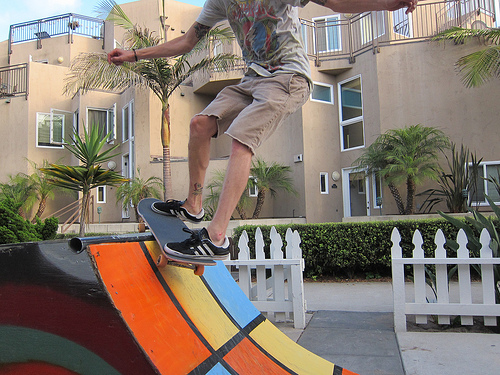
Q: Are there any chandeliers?
A: No, there are no chandeliers.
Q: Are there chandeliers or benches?
A: No, there are no chandeliers or benches.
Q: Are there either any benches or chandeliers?
A: No, there are no chandeliers or benches.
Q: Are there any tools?
A: No, there are no tools.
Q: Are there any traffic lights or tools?
A: No, there are no tools or traffic lights.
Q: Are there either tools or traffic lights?
A: No, there are no tools or traffic lights.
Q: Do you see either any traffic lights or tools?
A: No, there are no tools or traffic lights.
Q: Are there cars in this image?
A: No, there are no cars.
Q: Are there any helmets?
A: No, there are no helmets.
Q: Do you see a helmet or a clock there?
A: No, there are no helmets or clocks.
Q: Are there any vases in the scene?
A: No, there are no vases.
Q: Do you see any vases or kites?
A: No, there are no vases or kites.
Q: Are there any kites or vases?
A: No, there are no vases or kites.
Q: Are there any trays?
A: No, there are no trays.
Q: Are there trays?
A: No, there are no trays.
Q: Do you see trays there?
A: No, there are no trays.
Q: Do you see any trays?
A: No, there are no trays.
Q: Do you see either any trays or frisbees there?
A: No, there are no trays or frisbees.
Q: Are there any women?
A: No, there are no women.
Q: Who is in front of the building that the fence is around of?
A: The man is in front of the building.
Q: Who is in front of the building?
A: The man is in front of the building.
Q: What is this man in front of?
A: The man is in front of the building.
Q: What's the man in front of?
A: The man is in front of the building.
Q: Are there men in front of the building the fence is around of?
A: Yes, there is a man in front of the building.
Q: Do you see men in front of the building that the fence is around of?
A: Yes, there is a man in front of the building.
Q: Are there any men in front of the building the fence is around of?
A: Yes, there is a man in front of the building.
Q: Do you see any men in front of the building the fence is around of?
A: Yes, there is a man in front of the building.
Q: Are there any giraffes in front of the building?
A: No, there is a man in front of the building.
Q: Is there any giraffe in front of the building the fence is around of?
A: No, there is a man in front of the building.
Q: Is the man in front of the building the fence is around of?
A: Yes, the man is in front of the building.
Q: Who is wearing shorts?
A: The man is wearing shorts.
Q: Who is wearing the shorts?
A: The man is wearing shorts.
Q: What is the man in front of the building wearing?
A: The man is wearing shorts.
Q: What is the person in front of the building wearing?
A: The man is wearing shorts.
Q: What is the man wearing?
A: The man is wearing shorts.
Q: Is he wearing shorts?
A: Yes, the man is wearing shorts.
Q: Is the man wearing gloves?
A: No, the man is wearing shorts.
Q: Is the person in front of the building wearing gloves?
A: No, the man is wearing shorts.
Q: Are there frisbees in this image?
A: No, there are no frisbees.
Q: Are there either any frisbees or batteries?
A: No, there are no frisbees or batteries.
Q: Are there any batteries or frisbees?
A: No, there are no frisbees or batteries.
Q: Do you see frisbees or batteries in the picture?
A: No, there are no frisbees or batteries.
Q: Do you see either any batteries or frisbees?
A: No, there are no frisbees or batteries.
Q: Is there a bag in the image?
A: No, there are no bags.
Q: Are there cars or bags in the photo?
A: No, there are no bags or cars.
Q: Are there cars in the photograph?
A: No, there are no cars.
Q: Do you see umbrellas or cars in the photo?
A: No, there are no cars or umbrellas.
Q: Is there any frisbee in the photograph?
A: No, there are no frisbees.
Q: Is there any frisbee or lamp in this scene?
A: No, there are no frisbees or lamps.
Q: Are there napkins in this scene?
A: No, there are no napkins.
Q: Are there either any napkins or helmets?
A: No, there are no napkins or helmets.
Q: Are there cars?
A: No, there are no cars.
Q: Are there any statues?
A: No, there are no statues.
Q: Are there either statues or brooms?
A: No, there are no statues or brooms.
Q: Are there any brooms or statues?
A: No, there are no statues or brooms.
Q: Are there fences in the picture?
A: Yes, there is a fence.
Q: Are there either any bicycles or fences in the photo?
A: Yes, there is a fence.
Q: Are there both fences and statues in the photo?
A: No, there is a fence but no statues.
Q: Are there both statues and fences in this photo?
A: No, there is a fence but no statues.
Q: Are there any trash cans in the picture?
A: No, there are no trash cans.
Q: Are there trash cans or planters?
A: No, there are no trash cans or planters.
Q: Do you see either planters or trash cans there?
A: No, there are no trash cans or planters.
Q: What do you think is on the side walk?
A: The fence is on the side walk.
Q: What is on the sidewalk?
A: The fence is on the side walk.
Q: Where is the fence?
A: The fence is on the sidewalk.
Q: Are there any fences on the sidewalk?
A: Yes, there is a fence on the sidewalk.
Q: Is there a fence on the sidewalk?
A: Yes, there is a fence on the sidewalk.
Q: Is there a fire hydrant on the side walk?
A: No, there is a fence on the side walk.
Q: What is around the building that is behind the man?
A: The fence is around the building.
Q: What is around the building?
A: The fence is around the building.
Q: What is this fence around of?
A: The fence is around the building.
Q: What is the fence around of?
A: The fence is around the building.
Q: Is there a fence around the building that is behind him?
A: Yes, there is a fence around the building.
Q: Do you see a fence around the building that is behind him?
A: Yes, there is a fence around the building.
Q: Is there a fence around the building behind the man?
A: Yes, there is a fence around the building.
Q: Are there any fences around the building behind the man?
A: Yes, there is a fence around the building.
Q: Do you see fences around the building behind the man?
A: Yes, there is a fence around the building.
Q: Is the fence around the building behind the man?
A: Yes, the fence is around the building.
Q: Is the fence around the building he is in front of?
A: Yes, the fence is around the building.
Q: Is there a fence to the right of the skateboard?
A: Yes, there is a fence to the right of the skateboard.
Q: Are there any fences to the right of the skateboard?
A: Yes, there is a fence to the right of the skateboard.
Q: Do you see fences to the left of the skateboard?
A: No, the fence is to the right of the skateboard.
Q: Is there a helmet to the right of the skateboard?
A: No, there is a fence to the right of the skateboard.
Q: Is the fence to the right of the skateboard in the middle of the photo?
A: Yes, the fence is to the right of the skateboard.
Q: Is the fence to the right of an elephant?
A: No, the fence is to the right of the skateboard.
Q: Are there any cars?
A: No, there are no cars.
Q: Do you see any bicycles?
A: No, there are no bicycles.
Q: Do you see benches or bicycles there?
A: No, there are no bicycles or benches.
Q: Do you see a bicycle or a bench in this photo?
A: No, there are no bicycles or benches.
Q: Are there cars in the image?
A: No, there are no cars.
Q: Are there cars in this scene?
A: No, there are no cars.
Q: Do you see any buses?
A: No, there are no buses.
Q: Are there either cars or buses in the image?
A: No, there are no buses or cars.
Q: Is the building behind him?
A: Yes, the building is behind the man.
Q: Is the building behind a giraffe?
A: No, the building is behind the man.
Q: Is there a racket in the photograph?
A: No, there are no rackets.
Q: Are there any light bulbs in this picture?
A: No, there are no light bulbs.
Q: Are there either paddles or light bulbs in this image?
A: No, there are no light bulbs or paddles.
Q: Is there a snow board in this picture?
A: No, there are no snowboards.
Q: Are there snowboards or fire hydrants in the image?
A: No, there are no snowboards or fire hydrants.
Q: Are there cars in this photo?
A: No, there are no cars.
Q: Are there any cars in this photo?
A: No, there are no cars.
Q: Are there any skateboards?
A: Yes, there is a skateboard.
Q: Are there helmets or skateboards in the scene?
A: Yes, there is a skateboard.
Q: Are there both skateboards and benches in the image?
A: No, there is a skateboard but no benches.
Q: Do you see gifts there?
A: No, there are no gifts.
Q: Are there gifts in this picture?
A: No, there are no gifts.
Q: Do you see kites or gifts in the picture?
A: No, there are no gifts or kites.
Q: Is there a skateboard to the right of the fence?
A: No, the skateboard is to the left of the fence.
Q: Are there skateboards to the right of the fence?
A: No, the skateboard is to the left of the fence.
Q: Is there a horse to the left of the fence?
A: No, there is a skateboard to the left of the fence.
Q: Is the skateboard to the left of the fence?
A: Yes, the skateboard is to the left of the fence.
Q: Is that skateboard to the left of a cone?
A: No, the skateboard is to the left of the fence.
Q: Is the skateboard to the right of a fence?
A: No, the skateboard is to the left of a fence.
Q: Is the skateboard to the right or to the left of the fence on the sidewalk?
A: The skateboard is to the left of the fence.